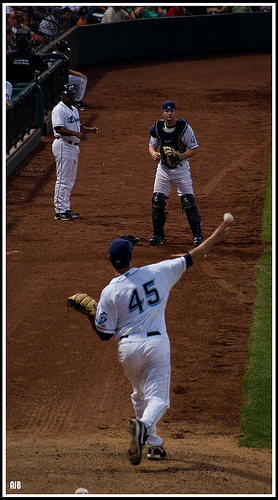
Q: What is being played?
A: Baseball.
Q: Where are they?
A: Baseball field.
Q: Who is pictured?
A: Team players.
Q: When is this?
A: Daytime.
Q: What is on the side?
A: Stands.